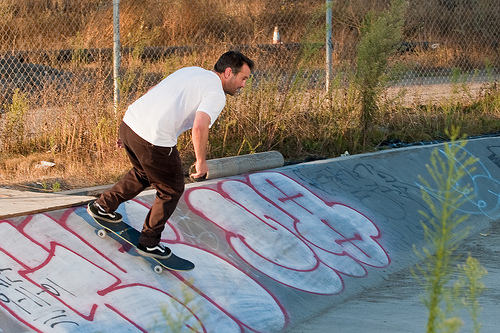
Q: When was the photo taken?
A: Daytime.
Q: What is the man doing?
A: Skateboarding.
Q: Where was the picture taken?
A: At a skatepark.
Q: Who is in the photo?
A: A man.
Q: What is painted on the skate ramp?
A: Graffiti.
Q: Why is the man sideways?
A: He is on the ramp.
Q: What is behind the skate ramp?
A: A chain link fence.